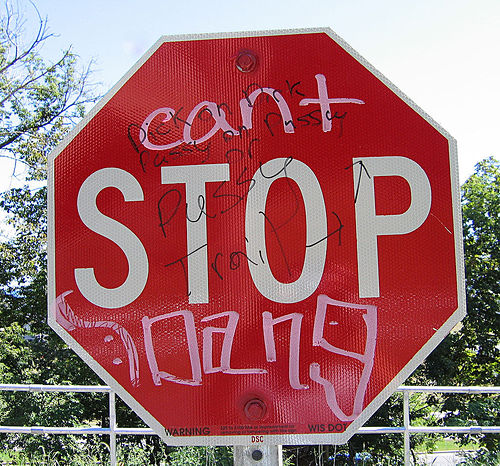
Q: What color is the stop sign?
A: Red.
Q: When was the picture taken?
A: During the day.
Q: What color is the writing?
A: White.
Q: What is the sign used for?
A: To let people know to stop.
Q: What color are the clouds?
A: White.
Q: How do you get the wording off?
A: You have to repaint the whole sign.